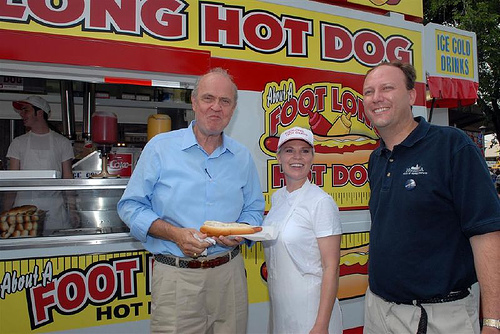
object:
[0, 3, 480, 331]
truck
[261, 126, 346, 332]
woman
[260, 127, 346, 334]
employee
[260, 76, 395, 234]
logo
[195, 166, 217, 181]
pen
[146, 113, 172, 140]
container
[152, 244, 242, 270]
belt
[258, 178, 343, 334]
apron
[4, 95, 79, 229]
employee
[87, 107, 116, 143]
ketchup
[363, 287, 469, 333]
belt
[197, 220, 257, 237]
hot dog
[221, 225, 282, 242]
paper wrapper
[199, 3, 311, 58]
words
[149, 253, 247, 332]
khakis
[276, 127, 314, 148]
cap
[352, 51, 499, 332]
man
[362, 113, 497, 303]
shirt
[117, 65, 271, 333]
man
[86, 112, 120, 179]
container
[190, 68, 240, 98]
hair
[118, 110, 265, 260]
shirt